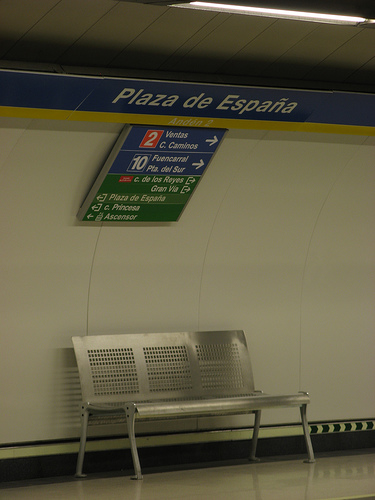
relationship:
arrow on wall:
[204, 135, 220, 148] [0, 68, 372, 482]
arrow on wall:
[190, 159, 207, 172] [0, 68, 372, 482]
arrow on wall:
[84, 212, 96, 222] [0, 68, 372, 482]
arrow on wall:
[96, 193, 103, 203] [0, 68, 372, 482]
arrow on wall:
[181, 186, 193, 194] [0, 68, 372, 482]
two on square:
[144, 131, 157, 147] [138, 129, 166, 148]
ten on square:
[132, 155, 148, 171] [127, 151, 154, 174]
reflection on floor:
[309, 467, 373, 477] [0, 447, 373, 500]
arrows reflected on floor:
[308, 420, 373, 434] [0, 447, 373, 500]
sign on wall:
[76, 122, 230, 225] [0, 68, 372, 482]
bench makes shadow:
[71, 328, 319, 481] [52, 346, 140, 423]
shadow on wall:
[52, 346, 140, 423] [0, 68, 372, 482]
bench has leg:
[71, 328, 319, 481] [76, 411, 87, 479]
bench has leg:
[71, 328, 319, 481] [123, 403, 143, 479]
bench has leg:
[71, 328, 319, 481] [249, 409, 264, 462]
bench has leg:
[71, 328, 319, 481] [299, 404, 315, 464]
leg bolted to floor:
[76, 411, 87, 479] [0, 447, 373, 500]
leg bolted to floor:
[123, 403, 143, 479] [0, 447, 373, 500]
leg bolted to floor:
[249, 409, 264, 462] [0, 447, 373, 500]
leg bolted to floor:
[299, 404, 315, 464] [0, 447, 373, 500]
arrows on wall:
[308, 420, 373, 434] [0, 68, 372, 482]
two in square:
[144, 131, 157, 147] [138, 129, 166, 148]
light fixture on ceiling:
[170, 0, 372, 27] [1, 2, 374, 91]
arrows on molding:
[308, 420, 373, 434] [1, 419, 374, 483]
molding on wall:
[1, 419, 374, 483] [0, 68, 372, 482]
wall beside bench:
[0, 68, 372, 482] [71, 328, 319, 481]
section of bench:
[142, 345, 198, 394] [71, 328, 319, 481]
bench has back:
[71, 328, 319, 481] [72, 329, 256, 402]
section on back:
[142, 345, 198, 394] [72, 329, 256, 402]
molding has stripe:
[1, 419, 374, 483] [0, 429, 374, 483]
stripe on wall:
[0, 429, 374, 483] [0, 68, 372, 482]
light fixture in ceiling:
[170, 0, 372, 27] [1, 2, 374, 91]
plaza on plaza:
[113, 87, 179, 110] [113, 87, 179, 110]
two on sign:
[144, 131, 157, 147] [76, 122, 230, 225]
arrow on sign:
[190, 159, 207, 172] [76, 122, 230, 225]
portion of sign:
[81, 175, 200, 224] [76, 122, 230, 225]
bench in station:
[71, 328, 319, 481] [0, 0, 372, 499]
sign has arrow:
[76, 122, 230, 225] [204, 135, 220, 148]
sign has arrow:
[76, 122, 230, 225] [190, 159, 207, 172]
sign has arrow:
[76, 122, 230, 225] [181, 186, 193, 194]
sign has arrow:
[76, 122, 230, 225] [96, 193, 103, 203]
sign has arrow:
[76, 122, 230, 225] [84, 212, 96, 222]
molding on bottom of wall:
[1, 419, 374, 483] [0, 68, 372, 482]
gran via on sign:
[150, 183, 179, 195] [76, 122, 230, 225]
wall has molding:
[0, 68, 372, 482] [1, 419, 374, 483]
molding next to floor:
[1, 419, 374, 483] [0, 447, 373, 500]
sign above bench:
[76, 122, 230, 225] [71, 328, 319, 481]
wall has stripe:
[0, 68, 372, 482] [0, 70, 374, 126]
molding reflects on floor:
[1, 419, 374, 483] [0, 447, 373, 500]